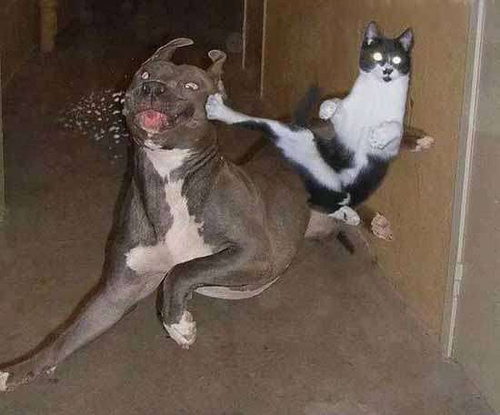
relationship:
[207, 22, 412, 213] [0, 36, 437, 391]
cat kicking dog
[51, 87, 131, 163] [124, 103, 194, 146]
spit from mouth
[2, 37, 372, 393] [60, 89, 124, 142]
dog spitting spit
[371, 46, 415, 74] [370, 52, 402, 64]
light in eyes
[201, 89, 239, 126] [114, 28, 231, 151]
foot in face